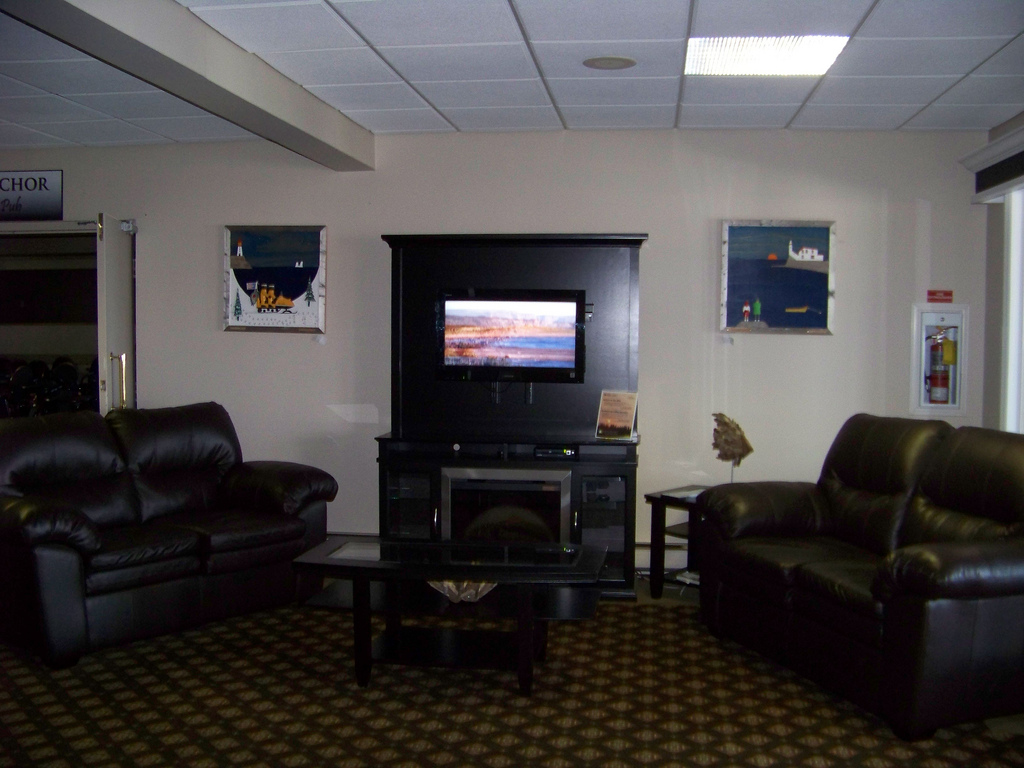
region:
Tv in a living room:
[432, 286, 594, 382]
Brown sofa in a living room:
[685, 418, 1021, 714]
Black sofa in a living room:
[5, 402, 338, 662]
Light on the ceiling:
[675, 23, 853, 77]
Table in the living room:
[292, 529, 641, 684]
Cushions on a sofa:
[735, 531, 891, 612]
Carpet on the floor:
[5, 595, 1015, 764]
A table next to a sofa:
[647, 478, 712, 593]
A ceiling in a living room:
[8, 3, 1014, 140]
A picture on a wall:
[711, 215, 842, 345]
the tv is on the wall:
[389, 253, 599, 375]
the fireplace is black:
[365, 376, 762, 659]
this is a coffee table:
[289, 502, 634, 642]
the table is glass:
[266, 505, 625, 662]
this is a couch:
[78, 408, 300, 647]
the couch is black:
[102, 446, 338, 665]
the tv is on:
[403, 285, 704, 460]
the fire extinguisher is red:
[924, 326, 950, 403]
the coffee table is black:
[292, 530, 609, 686]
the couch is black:
[4, 401, 338, 655]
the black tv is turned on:
[430, 293, 585, 385]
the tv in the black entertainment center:
[373, 231, 646, 604]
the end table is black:
[640, 484, 720, 602]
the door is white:
[90, 211, 135, 421]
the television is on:
[444, 281, 561, 371]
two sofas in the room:
[35, 383, 1020, 678]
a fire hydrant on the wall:
[915, 304, 961, 412]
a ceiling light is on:
[687, 29, 833, 99]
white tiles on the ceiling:
[386, 29, 587, 110]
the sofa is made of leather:
[751, 363, 976, 661]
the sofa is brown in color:
[675, 333, 1008, 716]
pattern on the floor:
[295, 682, 337, 696]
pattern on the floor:
[639, 632, 697, 671]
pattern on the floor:
[526, 691, 550, 723]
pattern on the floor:
[198, 746, 215, 756]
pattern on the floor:
[481, 682, 497, 712]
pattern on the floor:
[362, 651, 376, 675]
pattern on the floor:
[672, 633, 686, 665]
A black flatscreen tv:
[426, 282, 589, 387]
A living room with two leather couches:
[6, 190, 1015, 737]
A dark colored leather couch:
[1, 399, 335, 659]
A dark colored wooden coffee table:
[298, 528, 603, 693]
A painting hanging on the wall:
[713, 209, 834, 330]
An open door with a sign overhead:
[3, 167, 137, 408]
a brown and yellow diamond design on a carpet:
[18, 714, 80, 766]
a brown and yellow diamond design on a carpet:
[157, 707, 235, 765]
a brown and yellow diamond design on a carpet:
[234, 707, 308, 766]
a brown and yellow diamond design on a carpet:
[290, 701, 383, 762]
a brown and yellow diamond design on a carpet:
[376, 704, 437, 750]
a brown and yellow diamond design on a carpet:
[427, 708, 492, 763]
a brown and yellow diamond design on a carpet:
[490, 710, 563, 761]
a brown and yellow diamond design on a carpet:
[568, 705, 639, 764]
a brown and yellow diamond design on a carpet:
[645, 691, 706, 758]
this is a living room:
[109, 92, 951, 627]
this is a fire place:
[315, 219, 813, 618]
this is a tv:
[391, 256, 565, 370]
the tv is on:
[377, 208, 647, 395]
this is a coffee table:
[321, 469, 657, 684]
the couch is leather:
[710, 408, 1011, 669]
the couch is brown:
[713, 382, 999, 667]